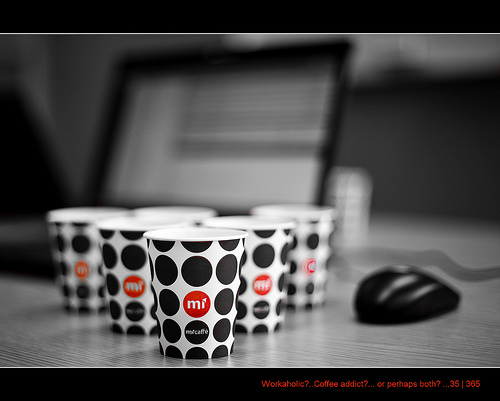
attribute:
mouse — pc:
[351, 250, 466, 322]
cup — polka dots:
[44, 204, 129, 318]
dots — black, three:
[156, 255, 241, 290]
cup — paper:
[137, 220, 252, 360]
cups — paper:
[43, 181, 364, 376]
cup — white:
[143, 225, 247, 360]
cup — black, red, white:
[140, 226, 234, 357]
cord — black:
[326, 237, 488, 287]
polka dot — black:
[177, 252, 215, 288]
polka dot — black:
[213, 250, 240, 286]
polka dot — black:
[155, 315, 184, 342]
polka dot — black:
[212, 316, 232, 342]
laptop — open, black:
[2, 37, 356, 284]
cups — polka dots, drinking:
[45, 199, 339, 359]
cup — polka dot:
[143, 219, 257, 377]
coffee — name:
[181, 288, 211, 348]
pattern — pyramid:
[42, 192, 340, 372]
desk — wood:
[4, 202, 499, 400]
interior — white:
[153, 233, 231, 240]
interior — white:
[104, 215, 175, 225]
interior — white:
[260, 202, 324, 216]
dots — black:
[151, 250, 240, 290]